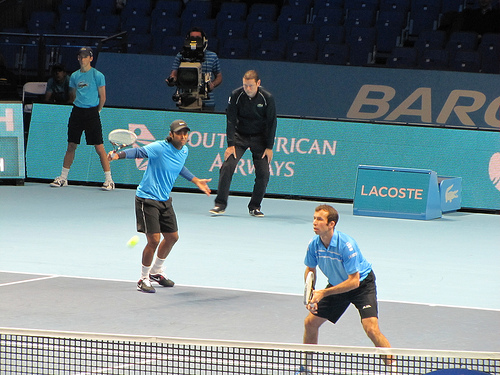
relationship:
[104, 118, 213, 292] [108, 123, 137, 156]
man with a racket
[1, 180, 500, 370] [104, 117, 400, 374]
court below men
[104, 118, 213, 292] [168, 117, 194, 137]
man with hat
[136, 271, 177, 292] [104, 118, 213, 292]
socks are on man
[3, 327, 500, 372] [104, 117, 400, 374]
net in front of people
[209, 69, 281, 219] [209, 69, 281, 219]
man wearing man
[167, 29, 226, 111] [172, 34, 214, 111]
man operating camera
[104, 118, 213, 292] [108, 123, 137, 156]
man holding racket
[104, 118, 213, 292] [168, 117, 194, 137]
man wearing a hat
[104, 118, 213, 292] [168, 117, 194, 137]
man wearing hat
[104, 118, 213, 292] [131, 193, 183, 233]
man wearing shorts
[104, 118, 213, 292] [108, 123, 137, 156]
man swinging racket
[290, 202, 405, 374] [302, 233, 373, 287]
man wearing blue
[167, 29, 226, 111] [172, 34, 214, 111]
man behind camera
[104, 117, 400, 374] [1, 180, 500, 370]
people are on court